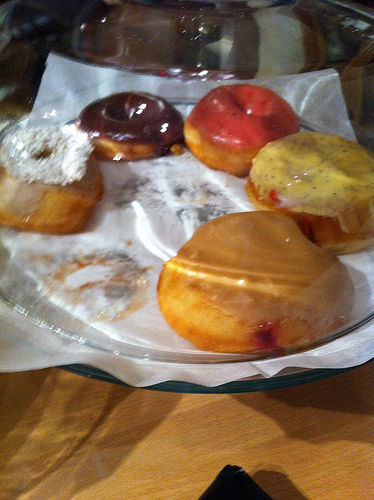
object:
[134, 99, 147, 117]
light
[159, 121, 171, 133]
light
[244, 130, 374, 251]
piece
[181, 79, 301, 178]
piece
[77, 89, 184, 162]
piece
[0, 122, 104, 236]
piece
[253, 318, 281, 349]
jelly filling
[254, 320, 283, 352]
hole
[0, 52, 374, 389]
paper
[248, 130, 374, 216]
icing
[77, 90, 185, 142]
icing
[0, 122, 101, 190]
powdered sugar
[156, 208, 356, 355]
caramel icing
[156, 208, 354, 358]
donut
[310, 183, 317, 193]
dark speck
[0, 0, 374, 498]
table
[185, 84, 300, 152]
frosting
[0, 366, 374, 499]
table top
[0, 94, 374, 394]
serving plate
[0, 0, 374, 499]
background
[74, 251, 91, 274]
food stain